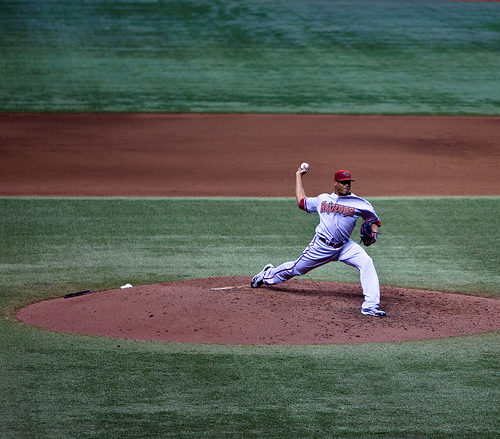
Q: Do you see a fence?
A: No, there are no fences.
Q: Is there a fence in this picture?
A: No, there are no fences.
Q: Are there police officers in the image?
A: No, there are no police officers.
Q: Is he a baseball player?
A: Yes, that is a baseball player.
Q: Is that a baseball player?
A: Yes, that is a baseball player.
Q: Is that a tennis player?
A: No, that is a baseball player.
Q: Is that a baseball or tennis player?
A: That is a baseball player.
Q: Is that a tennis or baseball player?
A: That is a baseball player.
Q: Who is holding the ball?
A: The player is holding the ball.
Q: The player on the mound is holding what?
A: The player is holding the ball.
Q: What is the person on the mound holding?
A: The player is holding the ball.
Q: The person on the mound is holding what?
A: The player is holding the ball.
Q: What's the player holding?
A: The player is holding the ball.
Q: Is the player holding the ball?
A: Yes, the player is holding the ball.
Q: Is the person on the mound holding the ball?
A: Yes, the player is holding the ball.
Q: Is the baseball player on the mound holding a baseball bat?
A: No, the player is holding the ball.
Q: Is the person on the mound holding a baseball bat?
A: No, the player is holding the ball.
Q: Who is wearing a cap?
A: The player is wearing a cap.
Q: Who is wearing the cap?
A: The player is wearing a cap.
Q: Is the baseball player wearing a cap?
A: Yes, the player is wearing a cap.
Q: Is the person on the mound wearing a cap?
A: Yes, the player is wearing a cap.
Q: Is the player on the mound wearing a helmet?
A: No, the player is wearing a cap.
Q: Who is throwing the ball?
A: The player is throwing the ball.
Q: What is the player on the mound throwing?
A: The player is throwing the ball.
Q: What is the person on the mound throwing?
A: The player is throwing the ball.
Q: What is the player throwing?
A: The player is throwing the ball.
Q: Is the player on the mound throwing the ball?
A: Yes, the player is throwing the ball.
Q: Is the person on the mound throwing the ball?
A: Yes, the player is throwing the ball.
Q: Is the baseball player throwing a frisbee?
A: No, the player is throwing the ball.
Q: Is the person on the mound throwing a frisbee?
A: No, the player is throwing the ball.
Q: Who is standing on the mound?
A: The player is standing on the mound.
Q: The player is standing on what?
A: The player is standing on the mound.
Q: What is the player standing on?
A: The player is standing on the mound.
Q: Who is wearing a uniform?
A: The player is wearing a uniform.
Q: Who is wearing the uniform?
A: The player is wearing a uniform.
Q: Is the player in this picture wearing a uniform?
A: Yes, the player is wearing a uniform.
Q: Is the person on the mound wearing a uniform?
A: Yes, the player is wearing a uniform.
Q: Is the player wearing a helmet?
A: No, the player is wearing a uniform.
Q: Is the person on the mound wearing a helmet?
A: No, the player is wearing a uniform.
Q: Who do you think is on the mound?
A: The player is on the mound.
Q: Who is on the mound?
A: The player is on the mound.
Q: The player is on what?
A: The player is on the mound.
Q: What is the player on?
A: The player is on the mound.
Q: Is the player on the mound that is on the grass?
A: Yes, the player is on the mound.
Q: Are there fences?
A: No, there are no fences.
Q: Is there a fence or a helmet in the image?
A: No, there are no fences or helmets.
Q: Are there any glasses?
A: No, there are no glasses.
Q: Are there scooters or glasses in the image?
A: No, there are no glasses or scooters.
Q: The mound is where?
A: The mound is on the grass.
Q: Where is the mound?
A: The mound is on the grass.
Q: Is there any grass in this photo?
A: Yes, there is grass.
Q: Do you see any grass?
A: Yes, there is grass.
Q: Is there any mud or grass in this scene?
A: Yes, there is grass.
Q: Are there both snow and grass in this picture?
A: No, there is grass but no snow.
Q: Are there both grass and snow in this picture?
A: No, there is grass but no snow.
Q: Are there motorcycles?
A: No, there are no motorcycles.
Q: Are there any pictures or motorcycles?
A: No, there are no motorcycles or pictures.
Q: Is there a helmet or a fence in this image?
A: No, there are no fences or helmets.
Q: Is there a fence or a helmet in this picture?
A: No, there are no fences or helmets.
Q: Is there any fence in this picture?
A: No, there are no fences.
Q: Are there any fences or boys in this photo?
A: No, there are no fences or boys.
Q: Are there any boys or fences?
A: No, there are no fences or boys.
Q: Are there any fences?
A: No, there are no fences.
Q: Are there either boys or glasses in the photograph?
A: No, there are no boys or glasses.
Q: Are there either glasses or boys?
A: No, there are no boys or glasses.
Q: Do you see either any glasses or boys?
A: No, there are no boys or glasses.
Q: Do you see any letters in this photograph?
A: Yes, there are letters.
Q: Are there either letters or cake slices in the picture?
A: Yes, there are letters.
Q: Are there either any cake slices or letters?
A: Yes, there are letters.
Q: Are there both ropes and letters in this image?
A: No, there are letters but no ropes.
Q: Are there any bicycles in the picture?
A: No, there are no bicycles.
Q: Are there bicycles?
A: No, there are no bicycles.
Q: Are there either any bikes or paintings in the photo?
A: No, there are no bikes or paintings.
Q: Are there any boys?
A: No, there are no boys.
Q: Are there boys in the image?
A: No, there are no boys.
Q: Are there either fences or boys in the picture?
A: No, there are no boys or fences.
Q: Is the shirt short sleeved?
A: Yes, the shirt is short sleeved.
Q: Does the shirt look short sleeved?
A: Yes, the shirt is short sleeved.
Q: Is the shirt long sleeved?
A: No, the shirt is short sleeved.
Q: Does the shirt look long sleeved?
A: No, the shirt is short sleeved.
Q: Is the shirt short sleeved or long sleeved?
A: The shirt is short sleeved.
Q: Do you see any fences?
A: No, there are no fences.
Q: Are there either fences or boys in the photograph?
A: No, there are no fences or boys.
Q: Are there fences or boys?
A: No, there are no fences or boys.